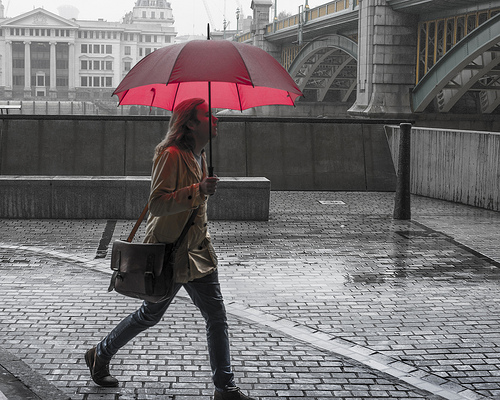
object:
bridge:
[222, 0, 499, 117]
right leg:
[93, 276, 182, 365]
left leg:
[182, 271, 235, 391]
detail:
[7, 26, 27, 36]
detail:
[27, 27, 53, 36]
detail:
[51, 28, 71, 38]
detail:
[2, 6, 76, 25]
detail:
[78, 29, 118, 40]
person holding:
[81, 23, 305, 400]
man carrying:
[104, 147, 216, 306]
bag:
[108, 203, 201, 303]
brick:
[0, 191, 500, 400]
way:
[27, 214, 101, 284]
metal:
[234, 0, 500, 116]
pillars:
[22, 39, 30, 99]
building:
[0, 0, 184, 100]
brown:
[96, 267, 237, 389]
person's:
[184, 264, 267, 400]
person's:
[84, 280, 187, 387]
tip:
[201, 21, 213, 43]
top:
[117, 10, 305, 115]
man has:
[212, 386, 255, 399]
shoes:
[83, 338, 118, 388]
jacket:
[143, 143, 217, 284]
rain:
[320, 214, 467, 328]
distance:
[123, 0, 272, 27]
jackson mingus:
[369, 309, 493, 399]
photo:
[0, 0, 500, 400]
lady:
[84, 96, 264, 400]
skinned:
[192, 103, 218, 141]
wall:
[0, 114, 394, 195]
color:
[109, 23, 308, 117]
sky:
[0, 0, 315, 45]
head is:
[172, 96, 218, 140]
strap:
[123, 148, 209, 244]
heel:
[81, 342, 103, 370]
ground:
[0, 190, 500, 399]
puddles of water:
[222, 232, 500, 304]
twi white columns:
[0, 19, 82, 91]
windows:
[17, 31, 135, 95]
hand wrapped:
[207, 165, 216, 196]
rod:
[205, 83, 213, 201]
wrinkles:
[98, 309, 302, 381]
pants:
[94, 270, 236, 388]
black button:
[187, 196, 193, 201]